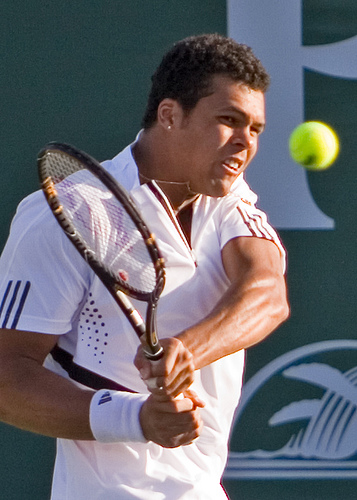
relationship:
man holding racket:
[0, 34, 292, 499] [34, 140, 167, 389]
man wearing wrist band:
[0, 34, 292, 499] [90, 388, 148, 446]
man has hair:
[0, 34, 292, 499] [141, 33, 269, 131]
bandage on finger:
[144, 377, 157, 389] [144, 364, 181, 389]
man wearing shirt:
[0, 34, 292, 499] [3, 128, 285, 499]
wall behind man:
[1, 1, 355, 498] [0, 34, 292, 499]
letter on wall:
[224, 0, 356, 234] [1, 1, 355, 498]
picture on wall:
[227, 338, 356, 482] [1, 1, 355, 498]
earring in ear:
[166, 125, 173, 132] [154, 96, 177, 133]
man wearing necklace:
[0, 34, 292, 499] [140, 169, 198, 198]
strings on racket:
[46, 153, 158, 290] [34, 140, 167, 389]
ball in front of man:
[288, 120, 341, 171] [0, 34, 292, 499]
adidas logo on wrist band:
[98, 388, 112, 406] [90, 388, 148, 446]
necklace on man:
[140, 169, 198, 198] [0, 34, 292, 499]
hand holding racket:
[130, 338, 198, 402] [34, 140, 167, 389]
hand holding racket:
[144, 390, 206, 450] [34, 140, 167, 389]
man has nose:
[0, 34, 292, 499] [233, 127, 256, 150]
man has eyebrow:
[0, 34, 292, 499] [216, 103, 248, 117]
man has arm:
[0, 34, 292, 499] [190, 236, 291, 370]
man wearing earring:
[0, 34, 292, 499] [166, 125, 173, 132]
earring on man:
[166, 125, 173, 132] [0, 34, 292, 499]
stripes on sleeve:
[1, 280, 31, 330] [1, 195, 89, 333]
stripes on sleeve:
[238, 206, 274, 241] [220, 182, 290, 274]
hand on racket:
[130, 338, 198, 402] [34, 140, 167, 389]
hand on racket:
[144, 390, 206, 450] [34, 140, 167, 389]